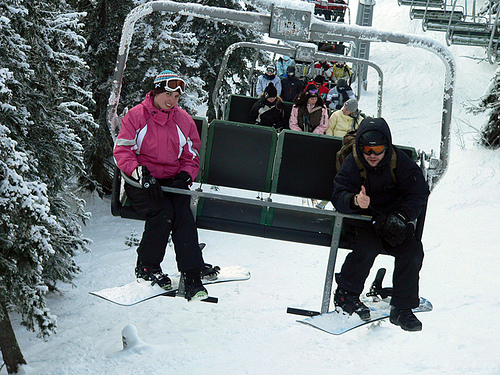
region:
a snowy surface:
[170, 335, 218, 364]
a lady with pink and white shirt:
[118, 115, 193, 165]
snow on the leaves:
[39, 86, 74, 116]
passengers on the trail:
[256, 25, 384, 152]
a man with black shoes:
[326, 286, 383, 342]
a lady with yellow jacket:
[334, 108, 356, 130]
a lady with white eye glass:
[151, 67, 195, 100]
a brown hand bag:
[328, 123, 355, 174]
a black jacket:
[345, 168, 365, 188]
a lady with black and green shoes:
[181, 266, 215, 303]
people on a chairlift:
[102, 21, 452, 364]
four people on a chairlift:
[252, 59, 357, 102]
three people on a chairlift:
[247, 78, 358, 134]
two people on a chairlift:
[115, 68, 426, 293]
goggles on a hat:
[150, 68, 190, 96]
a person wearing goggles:
[360, 136, 387, 158]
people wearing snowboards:
[84, 253, 459, 355]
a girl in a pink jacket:
[115, 91, 211, 193]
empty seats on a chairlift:
[201, 117, 341, 238]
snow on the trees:
[0, 5, 93, 357]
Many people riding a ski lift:
[90, 2, 461, 339]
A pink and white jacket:
[110, 89, 206, 184]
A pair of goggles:
[357, 139, 388, 159]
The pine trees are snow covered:
[1, 4, 273, 344]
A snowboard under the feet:
[294, 283, 439, 338]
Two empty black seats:
[194, 113, 351, 240]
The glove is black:
[381, 210, 410, 251]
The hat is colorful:
[146, 63, 183, 96]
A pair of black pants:
[336, 215, 426, 313]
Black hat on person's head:
[260, 79, 280, 105]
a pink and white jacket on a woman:
[114, 96, 203, 183]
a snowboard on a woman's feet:
[84, 260, 254, 319]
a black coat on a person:
[336, 114, 433, 231]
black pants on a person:
[332, 220, 424, 308]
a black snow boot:
[388, 303, 425, 333]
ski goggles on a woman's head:
[149, 78, 187, 97]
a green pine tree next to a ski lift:
[0, 1, 85, 374]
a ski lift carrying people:
[96, 0, 455, 325]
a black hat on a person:
[264, 80, 279, 97]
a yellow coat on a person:
[325, 109, 363, 139]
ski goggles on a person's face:
[358, 138, 388, 156]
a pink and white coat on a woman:
[114, 91, 207, 192]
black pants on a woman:
[130, 184, 207, 277]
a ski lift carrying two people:
[87, 0, 459, 336]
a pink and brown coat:
[289, 96, 333, 139]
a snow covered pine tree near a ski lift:
[3, 0, 90, 373]